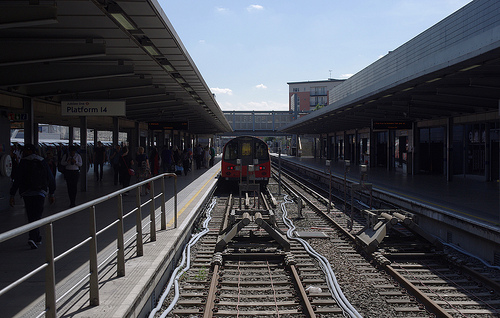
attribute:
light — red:
[228, 164, 233, 169]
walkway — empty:
[300, 115, 497, 224]